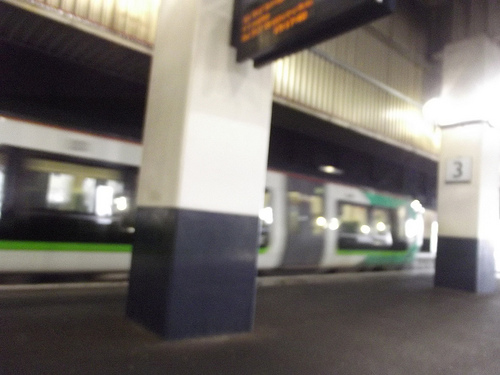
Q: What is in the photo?
A: A train.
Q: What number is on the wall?
A: 3.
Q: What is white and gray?
A: Column.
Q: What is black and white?
A: Pillars.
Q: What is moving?
A: Train.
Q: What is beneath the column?
A: The floor.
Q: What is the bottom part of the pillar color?
A: Black.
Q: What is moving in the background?
A: Train.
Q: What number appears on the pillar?
A: 3.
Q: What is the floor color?
A: Grey.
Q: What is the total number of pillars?
A: 2.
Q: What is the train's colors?
A: White and Green.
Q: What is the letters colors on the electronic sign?
A: Orange.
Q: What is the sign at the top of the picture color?
A: Black.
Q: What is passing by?
A: Train.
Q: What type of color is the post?
A: White and black.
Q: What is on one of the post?
A: A number.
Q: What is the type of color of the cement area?
A: Grey.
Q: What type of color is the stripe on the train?
A: Green.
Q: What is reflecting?
A: Windows.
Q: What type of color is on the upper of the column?
A: White.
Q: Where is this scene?
A: Subway.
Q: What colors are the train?
A: Green and white.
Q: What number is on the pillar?
A: 3.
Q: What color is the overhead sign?
A: Black.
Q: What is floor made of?
A: Cement.